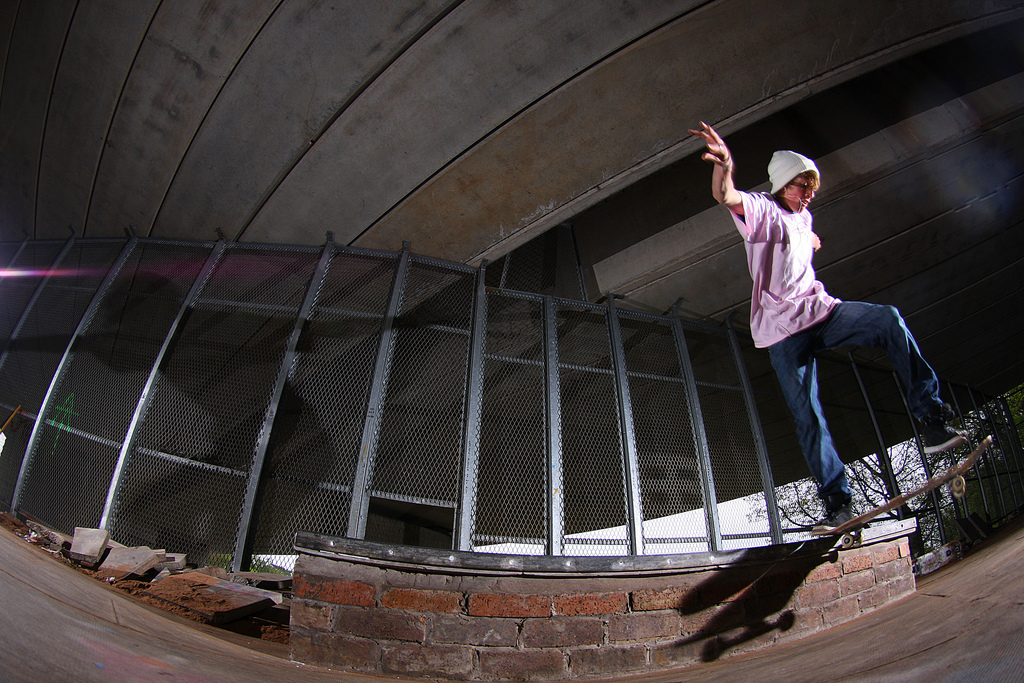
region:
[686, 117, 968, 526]
a skateboarder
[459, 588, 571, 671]
bricks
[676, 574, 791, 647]
a shadow on the brick wall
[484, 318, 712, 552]
the fence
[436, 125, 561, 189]
the ceiling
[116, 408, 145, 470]
the pole is grey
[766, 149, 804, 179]
a white beanie on the persons head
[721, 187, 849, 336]
tee is pink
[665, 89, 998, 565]
a person on a skateboard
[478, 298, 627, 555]
a silver metal fence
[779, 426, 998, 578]
a brown skateboard with wheels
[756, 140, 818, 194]
the person has a white hat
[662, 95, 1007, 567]
a person doing a skateboard trick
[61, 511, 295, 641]
a pile of broken bricks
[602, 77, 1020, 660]
man is doing a trick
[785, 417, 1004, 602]
this is a skateboard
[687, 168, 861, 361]
man wearing a pink shirt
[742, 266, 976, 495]
man wearing blue jeans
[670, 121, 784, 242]
man has arm raised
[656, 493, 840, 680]
shadow on the bricks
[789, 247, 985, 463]
man has leg bent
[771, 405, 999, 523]
man is wearing black shoes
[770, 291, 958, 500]
Person wearing pants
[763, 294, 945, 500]
Person wearing blue pants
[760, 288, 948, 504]
Person is wearing blue pants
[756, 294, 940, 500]
Person wearing jeans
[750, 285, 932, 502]
Person is wearing jeans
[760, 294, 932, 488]
Person is wearing blue jeans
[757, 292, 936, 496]
Person wearing blue jeans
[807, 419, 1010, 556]
Person is on a skateboard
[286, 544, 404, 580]
a brick in a wall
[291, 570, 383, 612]
a brick in a wall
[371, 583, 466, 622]
a brick in a wall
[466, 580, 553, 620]
a brick in a wall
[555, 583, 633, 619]
a brick in a wall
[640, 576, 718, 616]
a brick in a wall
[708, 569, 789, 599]
a brick in a wall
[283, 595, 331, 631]
a brick in a wall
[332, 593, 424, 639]
a brick in a wall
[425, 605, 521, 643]
a brick in a wall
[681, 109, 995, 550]
Kid riding a skateboard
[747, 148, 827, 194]
White beanie on a kid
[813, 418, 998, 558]
A large skateboard in the air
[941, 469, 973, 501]
The wheels of a skateboard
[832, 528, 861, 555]
The wheels of a skateboard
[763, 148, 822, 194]
bright white beanie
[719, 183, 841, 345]
light pink shirt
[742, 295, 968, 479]
dark blue denim jeans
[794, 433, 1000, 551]
normal wooden skateboard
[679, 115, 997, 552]
skateboarded preforming a trick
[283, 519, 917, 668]
small brick made ledge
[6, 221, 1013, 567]
large silver metal fence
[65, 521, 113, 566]
small broken piece of concrete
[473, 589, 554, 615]
old light red brick